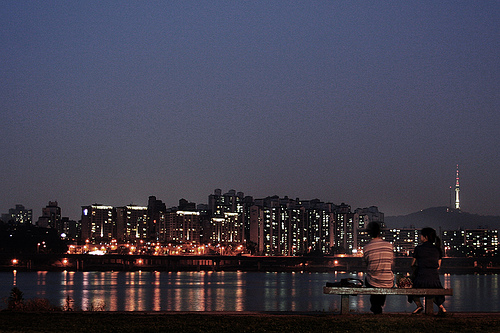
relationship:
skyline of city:
[3, 155, 499, 232] [2, 160, 499, 276]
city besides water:
[1, 186, 499, 270] [0, 264, 499, 311]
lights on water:
[2, 160, 499, 262] [0, 270, 498, 310]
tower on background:
[431, 170, 496, 238] [353, 192, 498, 223]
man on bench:
[360, 216, 395, 318] [321, 282, 454, 317]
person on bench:
[410, 226, 448, 314] [321, 282, 454, 317]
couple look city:
[359, 213, 454, 315] [0, 183, 496, 258]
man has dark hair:
[360, 221, 395, 314] [366, 219, 441, 254]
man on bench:
[360, 221, 395, 314] [321, 282, 454, 317]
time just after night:
[121, 87, 448, 223] [0, 0, 500, 333]